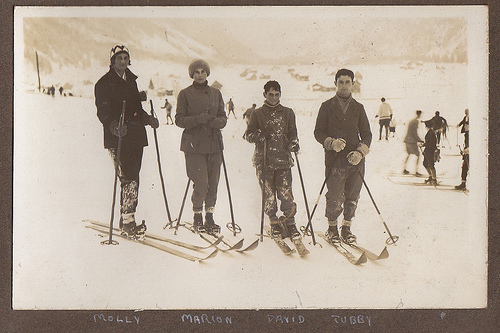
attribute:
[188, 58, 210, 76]
hat — fur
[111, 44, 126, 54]
hat — zig zagged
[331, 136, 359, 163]
gloves — white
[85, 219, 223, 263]
skiis — being used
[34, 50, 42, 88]
post — tall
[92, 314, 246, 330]
names — molly, marian, at the bottom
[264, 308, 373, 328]
names — david, tubby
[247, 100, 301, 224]
person — hatless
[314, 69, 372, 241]
kid — posing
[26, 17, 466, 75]
mountain — snowy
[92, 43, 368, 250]
family — skiing, in the snow, in the mountains, getting exercise, using skiis, holding ski poles, wearing clothes, out in the daytime, enjoying the day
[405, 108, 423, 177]
woman — skiing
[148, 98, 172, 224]
skii pole — pointy